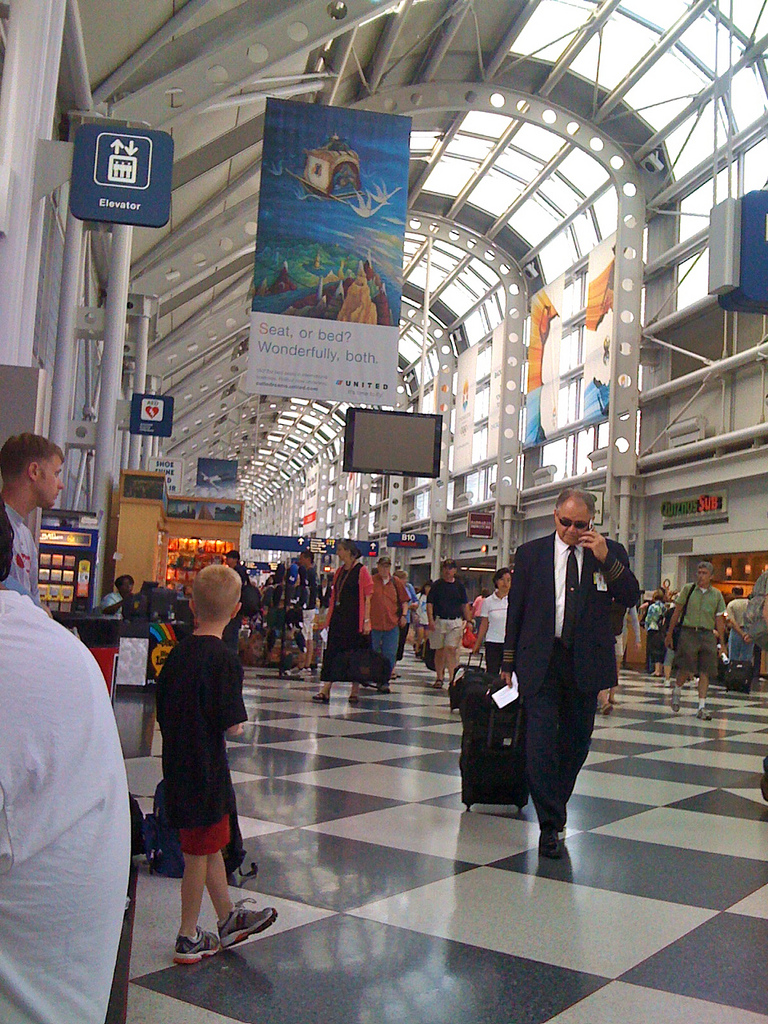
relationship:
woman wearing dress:
[312, 536, 384, 716] [307, 557, 367, 684]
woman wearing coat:
[312, 536, 384, 716] [317, 561, 370, 633]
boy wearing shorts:
[152, 571, 274, 973] [171, 808, 242, 863]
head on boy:
[186, 558, 250, 648] [152, 571, 274, 973]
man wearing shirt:
[663, 554, 735, 725] [676, 575, 726, 636]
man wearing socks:
[663, 554, 735, 725] [697, 695, 713, 715]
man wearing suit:
[489, 485, 642, 866] [506, 531, 644, 836]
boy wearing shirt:
[152, 570, 274, 972] [157, 633, 250, 824]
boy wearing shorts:
[152, 570, 274, 972] [169, 814, 236, 867]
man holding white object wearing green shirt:
[663, 560, 731, 726] [685, 590, 711, 624]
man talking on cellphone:
[489, 485, 641, 866] [580, 526, 596, 553]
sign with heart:
[128, 386, 181, 446] [142, 404, 161, 420]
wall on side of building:
[266, 613, 374, 730] [14, 22, 747, 796]